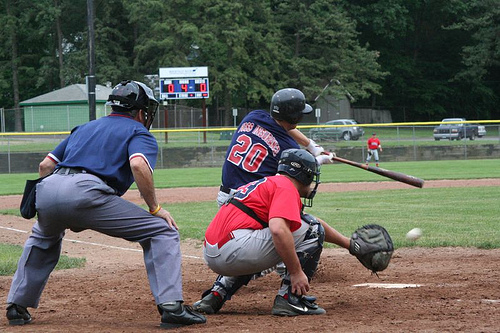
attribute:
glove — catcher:
[348, 222, 397, 273]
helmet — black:
[258, 82, 310, 119]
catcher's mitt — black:
[344, 217, 408, 283]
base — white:
[352, 279, 424, 294]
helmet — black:
[270, 85, 309, 118]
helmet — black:
[279, 144, 326, 196]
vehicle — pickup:
[434, 113, 479, 138]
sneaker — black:
[156, 299, 206, 327]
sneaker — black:
[5, 301, 34, 325]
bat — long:
[319, 148, 429, 190]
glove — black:
[342, 217, 397, 283]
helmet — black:
[272, 147, 319, 189]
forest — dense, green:
[127, 17, 402, 115]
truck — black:
[433, 114, 480, 141]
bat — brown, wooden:
[328, 149, 425, 197]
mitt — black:
[347, 222, 393, 277]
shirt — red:
[200, 172, 303, 252]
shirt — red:
[202, 172, 307, 242]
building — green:
[20, 78, 116, 135]